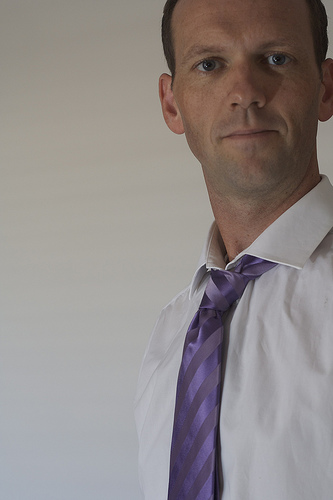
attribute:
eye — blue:
[189, 43, 226, 83]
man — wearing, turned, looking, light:
[141, 8, 321, 238]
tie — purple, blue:
[162, 257, 274, 462]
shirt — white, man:
[231, 280, 322, 470]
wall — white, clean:
[23, 74, 166, 267]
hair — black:
[158, 21, 177, 47]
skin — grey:
[221, 199, 275, 243]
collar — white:
[262, 200, 314, 277]